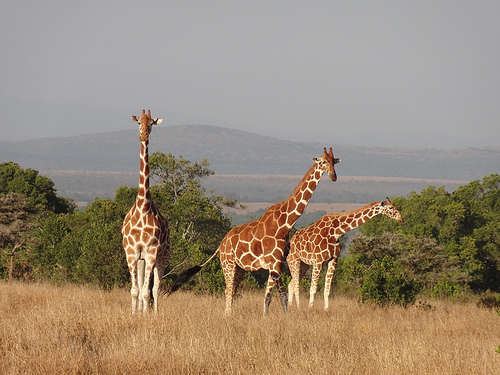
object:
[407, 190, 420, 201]
leaves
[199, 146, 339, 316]
giraffe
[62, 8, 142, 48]
clouds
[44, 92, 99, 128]
clouds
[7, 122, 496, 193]
mountains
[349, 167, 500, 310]
trees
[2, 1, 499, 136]
sky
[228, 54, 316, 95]
clouds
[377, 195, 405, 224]
giraffe head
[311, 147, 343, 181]
giraffe head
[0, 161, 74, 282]
trees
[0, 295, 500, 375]
ground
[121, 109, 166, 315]
animals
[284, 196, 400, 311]
giraffe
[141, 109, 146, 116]
horns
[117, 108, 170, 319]
giraffe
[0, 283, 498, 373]
grass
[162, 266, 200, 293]
tip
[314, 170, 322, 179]
spot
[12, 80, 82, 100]
clouds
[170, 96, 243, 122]
clouds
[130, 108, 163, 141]
head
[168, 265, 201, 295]
hair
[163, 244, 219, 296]
tail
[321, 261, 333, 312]
legs